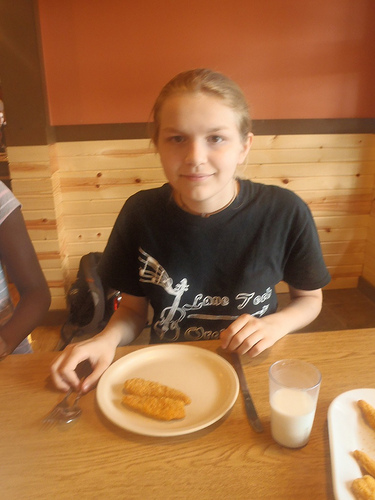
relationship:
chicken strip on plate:
[117, 390, 189, 426] [92, 340, 244, 444]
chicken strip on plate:
[117, 375, 195, 407] [92, 340, 244, 444]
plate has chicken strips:
[92, 340, 244, 444] [117, 375, 195, 425]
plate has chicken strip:
[92, 340, 244, 444] [117, 375, 195, 407]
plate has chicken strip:
[92, 340, 244, 444] [117, 390, 189, 426]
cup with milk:
[264, 354, 325, 453] [265, 382, 320, 453]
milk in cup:
[265, 382, 320, 453] [264, 354, 325, 453]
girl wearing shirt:
[45, 65, 331, 395] [92, 176, 333, 347]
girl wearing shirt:
[1, 172, 57, 365] [1, 176, 32, 354]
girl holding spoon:
[45, 65, 331, 395] [49, 373, 91, 429]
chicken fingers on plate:
[117, 375, 195, 425] [92, 340, 244, 444]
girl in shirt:
[45, 65, 331, 395] [92, 176, 333, 347]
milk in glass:
[265, 382, 320, 453] [264, 354, 325, 453]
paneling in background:
[1, 131, 375, 309] [2, 2, 374, 331]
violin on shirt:
[148, 276, 193, 344] [92, 176, 333, 347]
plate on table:
[92, 340, 244, 444] [1, 327, 373, 499]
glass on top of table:
[264, 354, 325, 453] [1, 327, 373, 499]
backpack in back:
[56, 253, 116, 344] [2, 2, 374, 331]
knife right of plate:
[223, 344, 267, 439] [92, 340, 244, 444]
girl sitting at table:
[45, 65, 331, 395] [1, 327, 373, 499]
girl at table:
[45, 65, 331, 395] [1, 327, 373, 499]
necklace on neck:
[168, 178, 242, 221] [169, 177, 247, 215]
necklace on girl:
[168, 178, 242, 221] [45, 65, 331, 395]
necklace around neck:
[168, 178, 242, 221] [169, 177, 247, 215]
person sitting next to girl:
[1, 172, 57, 365] [45, 65, 331, 395]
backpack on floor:
[56, 253, 116, 344] [31, 284, 374, 352]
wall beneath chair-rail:
[1, 131, 375, 309] [1, 113, 375, 151]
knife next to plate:
[223, 344, 267, 439] [92, 340, 244, 444]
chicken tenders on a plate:
[117, 375, 195, 425] [92, 340, 244, 444]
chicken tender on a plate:
[117, 390, 189, 426] [92, 340, 244, 444]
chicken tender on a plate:
[117, 375, 195, 407] [92, 340, 244, 444]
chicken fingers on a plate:
[117, 375, 195, 425] [92, 340, 244, 444]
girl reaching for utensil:
[45, 65, 331, 395] [49, 373, 91, 429]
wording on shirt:
[180, 285, 275, 343] [92, 176, 333, 347]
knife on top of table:
[223, 344, 267, 439] [1, 327, 373, 499]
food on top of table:
[116, 373, 374, 500] [1, 327, 373, 499]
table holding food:
[1, 327, 373, 499] [116, 373, 374, 500]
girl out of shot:
[1, 172, 57, 365] [2, 2, 373, 499]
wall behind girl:
[1, 131, 375, 309] [45, 65, 331, 395]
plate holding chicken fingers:
[92, 340, 244, 444] [117, 375, 195, 425]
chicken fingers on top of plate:
[117, 375, 195, 425] [92, 340, 244, 444]